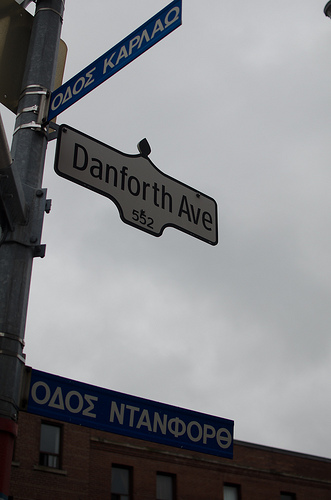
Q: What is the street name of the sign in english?
A: Danforth Ave.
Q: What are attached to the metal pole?
A: Signs.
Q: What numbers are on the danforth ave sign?
A: 552.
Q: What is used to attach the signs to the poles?
A: Bolts.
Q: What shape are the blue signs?
A: Rectangles.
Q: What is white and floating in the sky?
A: Clouds.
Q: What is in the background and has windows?
A: A building.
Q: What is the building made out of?
A: Bricks.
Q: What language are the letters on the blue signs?
A: Greek.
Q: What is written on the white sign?
A: Danforth Ave.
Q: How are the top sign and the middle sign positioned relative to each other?
A: Perpendicular.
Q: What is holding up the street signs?
A: Metal pole.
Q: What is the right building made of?
A: Brownish brick.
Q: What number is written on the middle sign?
A: 552.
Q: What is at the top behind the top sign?
A: Sign facing opposite direction.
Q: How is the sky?
A: Cloudy and overcast.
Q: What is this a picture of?
A: A street sign.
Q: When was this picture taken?
A: Daytime.